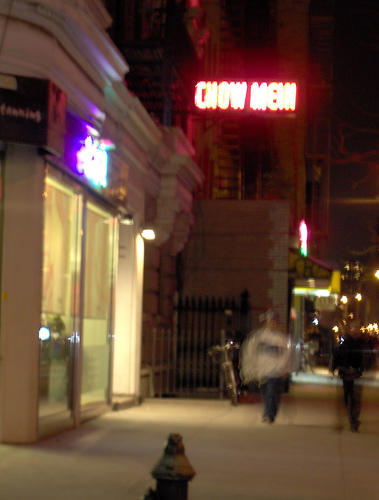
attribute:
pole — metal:
[158, 330, 165, 398]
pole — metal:
[163, 325, 172, 395]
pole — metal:
[170, 326, 179, 395]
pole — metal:
[176, 328, 185, 399]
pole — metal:
[184, 328, 190, 397]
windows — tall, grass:
[37, 170, 118, 428]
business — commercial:
[0, 0, 195, 440]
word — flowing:
[188, 80, 245, 114]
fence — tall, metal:
[146, 285, 252, 397]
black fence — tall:
[163, 277, 255, 403]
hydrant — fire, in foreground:
[141, 431, 197, 498]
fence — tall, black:
[151, 281, 253, 393]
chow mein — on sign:
[189, 80, 299, 111]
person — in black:
[320, 330, 370, 436]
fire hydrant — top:
[111, 399, 247, 498]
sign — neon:
[194, 78, 294, 112]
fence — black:
[175, 286, 250, 392]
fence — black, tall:
[153, 284, 265, 391]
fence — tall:
[165, 283, 278, 407]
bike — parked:
[198, 332, 255, 409]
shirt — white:
[240, 312, 306, 392]